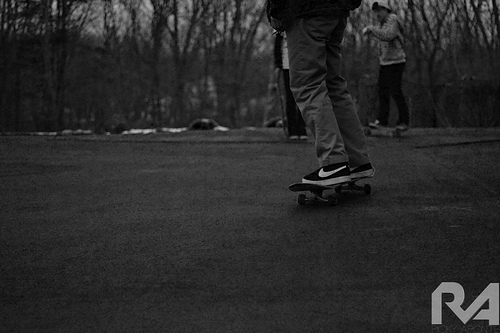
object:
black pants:
[372, 59, 409, 128]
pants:
[274, 68, 307, 137]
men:
[261, 0, 375, 202]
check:
[315, 161, 349, 181]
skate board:
[287, 170, 377, 206]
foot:
[297, 164, 356, 189]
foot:
[350, 161, 381, 180]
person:
[269, 30, 307, 146]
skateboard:
[367, 121, 417, 138]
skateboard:
[275, 68, 296, 142]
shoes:
[301, 163, 352, 185]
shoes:
[395, 126, 410, 132]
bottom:
[299, 177, 355, 189]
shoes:
[350, 159, 376, 180]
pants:
[282, 10, 376, 188]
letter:
[463, 278, 500, 333]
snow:
[121, 122, 192, 136]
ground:
[0, 133, 286, 333]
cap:
[370, 0, 398, 15]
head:
[369, 1, 393, 23]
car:
[188, 114, 234, 136]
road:
[0, 117, 499, 138]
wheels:
[296, 192, 307, 206]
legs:
[286, 6, 353, 188]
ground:
[292, 205, 500, 332]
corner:
[426, 277, 500, 333]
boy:
[360, 1, 413, 131]